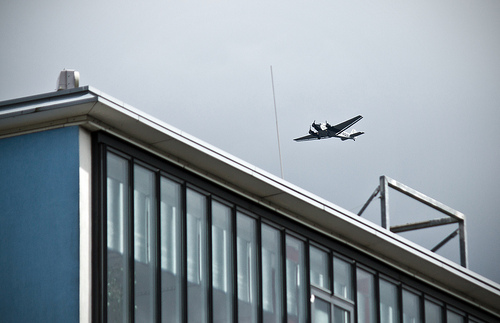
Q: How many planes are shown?
A: 1.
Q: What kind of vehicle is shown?
A: Airplane.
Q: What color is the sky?
A: Gray.